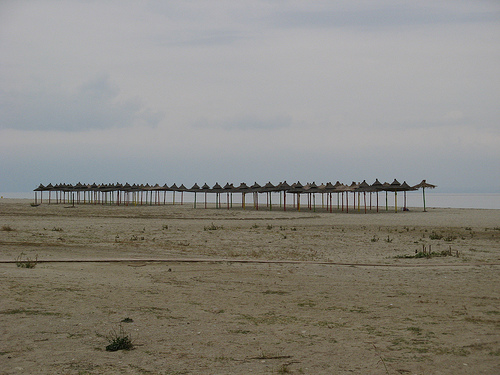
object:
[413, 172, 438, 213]
beach umbrella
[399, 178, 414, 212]
beach umbrella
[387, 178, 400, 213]
beach umbrella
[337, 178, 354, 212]
beach umbrella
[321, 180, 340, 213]
beach umbrella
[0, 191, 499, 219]
beach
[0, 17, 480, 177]
sky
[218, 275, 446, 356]
area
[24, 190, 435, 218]
poles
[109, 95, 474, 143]
cloud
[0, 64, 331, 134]
cloud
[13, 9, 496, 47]
cloud